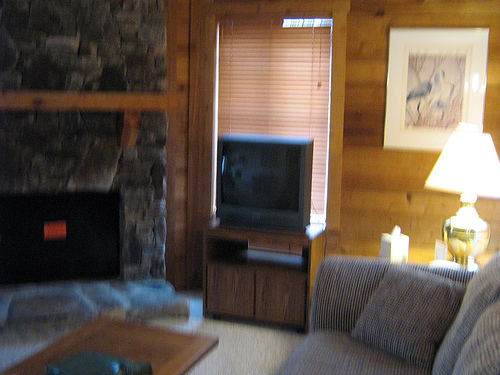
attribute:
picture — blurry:
[2, 1, 497, 372]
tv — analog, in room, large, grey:
[215, 130, 313, 233]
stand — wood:
[205, 220, 327, 332]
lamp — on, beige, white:
[425, 131, 499, 273]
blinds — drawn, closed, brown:
[219, 17, 327, 216]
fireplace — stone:
[1, 2, 189, 320]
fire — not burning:
[1, 192, 121, 288]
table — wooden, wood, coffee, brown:
[3, 315, 219, 372]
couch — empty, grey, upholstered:
[269, 254, 499, 371]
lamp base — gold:
[445, 215, 490, 270]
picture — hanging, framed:
[381, 26, 490, 154]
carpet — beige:
[7, 293, 310, 374]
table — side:
[406, 244, 499, 279]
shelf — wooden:
[1, 88, 181, 146]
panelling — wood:
[168, 3, 499, 286]